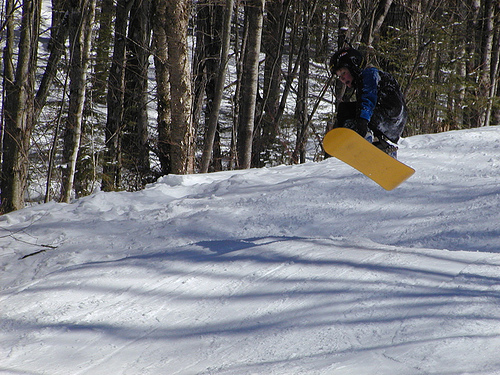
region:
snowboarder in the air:
[303, 35, 422, 193]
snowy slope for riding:
[126, 205, 375, 322]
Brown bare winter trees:
[49, 38, 240, 151]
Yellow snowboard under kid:
[316, 125, 424, 195]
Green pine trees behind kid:
[423, 32, 486, 117]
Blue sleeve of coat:
[359, 67, 386, 128]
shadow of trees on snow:
[176, 220, 271, 272]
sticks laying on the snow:
[14, 234, 56, 266]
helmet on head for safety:
[326, 44, 365, 70]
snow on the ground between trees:
[313, 47, 328, 107]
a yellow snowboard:
[310, 112, 430, 204]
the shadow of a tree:
[2, 225, 497, 355]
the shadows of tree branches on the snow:
[1, 228, 497, 353]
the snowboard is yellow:
[315, 116, 417, 201]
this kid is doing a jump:
[309, 27, 446, 204]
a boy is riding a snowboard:
[302, 32, 447, 207]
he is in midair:
[277, 33, 437, 203]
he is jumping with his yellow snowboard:
[303, 34, 420, 194]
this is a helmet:
[323, 41, 363, 73]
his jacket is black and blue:
[351, 61, 412, 143]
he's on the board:
[330, 125, 402, 166]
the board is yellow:
[375, 159, 398, 181]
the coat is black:
[383, 105, 398, 122]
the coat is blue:
[364, 73, 378, 91]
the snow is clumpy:
[181, 178, 237, 198]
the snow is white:
[411, 326, 469, 373]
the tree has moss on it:
[96, 42, 106, 75]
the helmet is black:
[330, 52, 355, 66]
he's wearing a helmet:
[326, 61, 350, 75]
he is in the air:
[305, 41, 438, 209]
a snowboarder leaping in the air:
[280, 42, 429, 192]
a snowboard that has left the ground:
[318, 120, 420, 210]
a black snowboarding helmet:
[319, 48, 368, 93]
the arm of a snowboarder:
[355, 66, 380, 136]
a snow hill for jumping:
[58, 205, 458, 372]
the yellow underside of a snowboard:
[315, 128, 415, 195]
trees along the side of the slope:
[6, 0, 301, 209]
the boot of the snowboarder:
[333, 118, 375, 148]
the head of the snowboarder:
[320, 46, 368, 88]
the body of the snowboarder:
[326, 45, 417, 150]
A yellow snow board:
[317, 118, 424, 195]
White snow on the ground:
[71, 225, 446, 356]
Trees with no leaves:
[28, 28, 285, 193]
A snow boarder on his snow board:
[286, 37, 433, 222]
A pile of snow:
[89, 173, 210, 235]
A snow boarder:
[316, 39, 414, 164]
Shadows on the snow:
[154, 225, 322, 264]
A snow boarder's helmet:
[319, 36, 371, 88]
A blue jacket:
[344, 60, 412, 139]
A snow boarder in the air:
[227, 2, 461, 232]